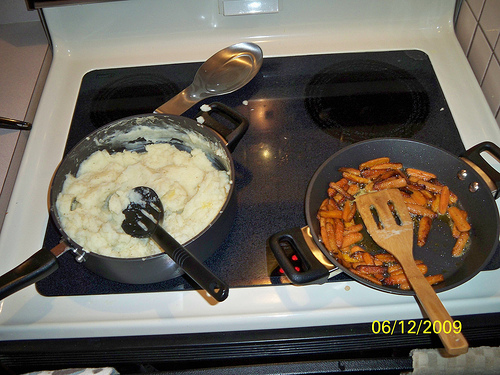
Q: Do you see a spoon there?
A: Yes, there is a spoon.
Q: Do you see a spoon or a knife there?
A: Yes, there is a spoon.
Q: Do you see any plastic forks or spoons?
A: Yes, there is a plastic spoon.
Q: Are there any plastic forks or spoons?
A: Yes, there is a plastic spoon.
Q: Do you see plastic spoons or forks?
A: Yes, there is a plastic spoon.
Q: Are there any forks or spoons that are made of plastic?
A: Yes, the spoon is made of plastic.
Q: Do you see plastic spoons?
A: Yes, there is a spoon that is made of plastic.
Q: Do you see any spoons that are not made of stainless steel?
A: Yes, there is a spoon that is made of plastic.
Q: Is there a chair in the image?
A: No, there are no chairs.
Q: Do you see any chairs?
A: No, there are no chairs.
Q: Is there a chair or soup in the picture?
A: No, there are no chairs or soup.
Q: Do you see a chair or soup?
A: No, there are no chairs or soup.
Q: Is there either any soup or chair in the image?
A: No, there are no chairs or soup.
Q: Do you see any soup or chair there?
A: No, there are no chairs or soup.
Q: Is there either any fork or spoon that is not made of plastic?
A: No, there is a spoon but it is made of plastic.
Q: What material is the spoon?
A: The spoon is made of plastic.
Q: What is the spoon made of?
A: The spoon is made of plastic.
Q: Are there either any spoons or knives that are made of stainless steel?
A: No, there is a spoon but it is made of plastic.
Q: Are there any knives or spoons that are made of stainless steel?
A: No, there is a spoon but it is made of plastic.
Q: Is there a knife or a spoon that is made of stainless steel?
A: No, there is a spoon but it is made of plastic.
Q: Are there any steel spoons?
A: No, there is a spoon but it is made of plastic.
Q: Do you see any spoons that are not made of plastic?
A: No, there is a spoon but it is made of plastic.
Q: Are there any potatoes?
A: Yes, there is a potato.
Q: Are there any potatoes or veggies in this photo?
A: Yes, there is a potato.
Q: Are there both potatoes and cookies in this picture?
A: No, there is a potato but no cookies.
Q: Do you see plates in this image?
A: No, there are no plates.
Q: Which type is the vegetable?
A: The vegetable is a potato.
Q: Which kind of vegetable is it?
A: The vegetable is a potato.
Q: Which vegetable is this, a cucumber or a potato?
A: That is a potato.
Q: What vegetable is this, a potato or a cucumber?
A: That is a potato.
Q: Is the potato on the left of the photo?
A: Yes, the potato is on the left of the image.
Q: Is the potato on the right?
A: No, the potato is on the left of the image.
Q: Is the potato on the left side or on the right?
A: The potato is on the left of the image.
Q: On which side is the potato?
A: The potato is on the left of the image.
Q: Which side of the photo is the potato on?
A: The potato is on the left of the image.